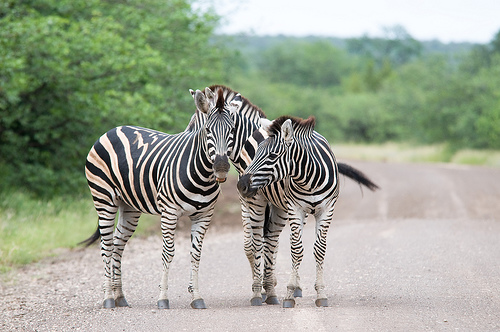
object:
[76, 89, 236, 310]
zebra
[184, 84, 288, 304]
zebra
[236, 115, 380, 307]
zebra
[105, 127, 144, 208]
stripes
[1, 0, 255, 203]
trees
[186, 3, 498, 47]
sky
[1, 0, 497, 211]
hill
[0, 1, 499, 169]
background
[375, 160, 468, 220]
tracks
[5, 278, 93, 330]
gravel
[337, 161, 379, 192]
tail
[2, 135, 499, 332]
road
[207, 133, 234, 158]
faces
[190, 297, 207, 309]
hoof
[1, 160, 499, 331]
ground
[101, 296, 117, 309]
hooves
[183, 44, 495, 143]
vegetation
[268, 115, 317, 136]
mane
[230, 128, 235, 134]
eyes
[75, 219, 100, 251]
tail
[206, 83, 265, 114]
manes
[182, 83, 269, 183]
each other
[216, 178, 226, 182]
tongue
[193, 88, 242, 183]
head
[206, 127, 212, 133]
eye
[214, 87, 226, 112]
mane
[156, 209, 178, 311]
front legs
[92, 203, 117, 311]
back legs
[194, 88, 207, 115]
ear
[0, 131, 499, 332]
area